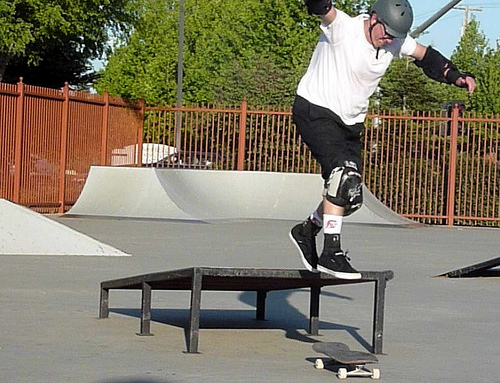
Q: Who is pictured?
A: A man.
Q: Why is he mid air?
A: To jump on his skateboard.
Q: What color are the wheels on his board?
A: White.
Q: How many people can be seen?
A: Just one.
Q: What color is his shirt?
A: It is white.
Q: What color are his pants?
A: They are black.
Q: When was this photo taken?
A: During the day.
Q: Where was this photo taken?
A: At a skatepark.